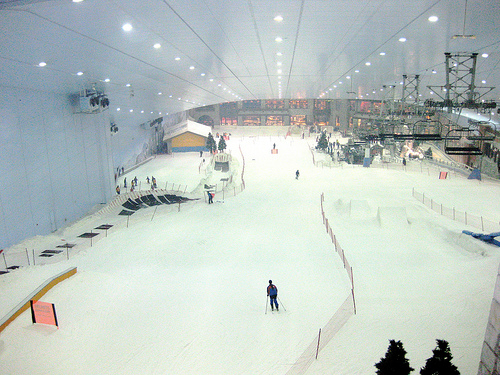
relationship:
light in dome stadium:
[272, 34, 282, 44] [2, 2, 479, 118]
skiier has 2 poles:
[261, 277, 282, 314] [263, 292, 288, 315]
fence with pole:
[281, 189, 367, 371] [317, 324, 323, 358]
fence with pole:
[281, 189, 367, 371] [351, 282, 359, 314]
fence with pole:
[281, 189, 367, 371] [340, 245, 348, 266]